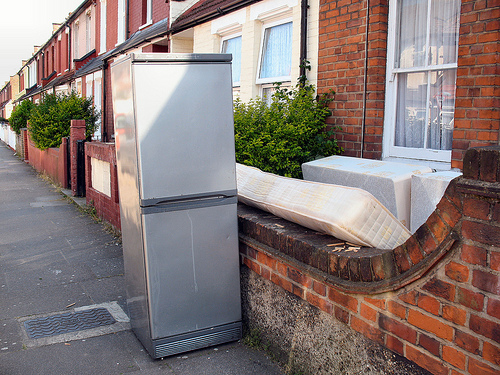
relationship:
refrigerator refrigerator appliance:
[104, 46, 247, 317] [111, 53, 243, 359]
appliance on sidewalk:
[104, 46, 247, 317] [10, 169, 73, 367]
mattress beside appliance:
[235, 158, 410, 259] [101, 50, 248, 357]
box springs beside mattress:
[237, 141, 411, 238] [239, 169, 387, 246]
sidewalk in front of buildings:
[0, 143, 144, 346] [18, 55, 109, 189]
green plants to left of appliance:
[234, 58, 332, 178] [101, 50, 248, 357]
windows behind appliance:
[378, 1, 450, 156] [96, 50, 257, 363]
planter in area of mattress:
[27, 94, 87, 157] [247, 154, 383, 236]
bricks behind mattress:
[462, 71, 493, 103] [254, 163, 396, 253]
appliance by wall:
[111, 53, 243, 359] [76, 141, 479, 365]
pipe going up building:
[357, 1, 371, 157] [174, 5, 484, 247]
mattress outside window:
[235, 158, 410, 259] [383, 2, 462, 165]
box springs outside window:
[237, 141, 411, 238] [383, 2, 462, 165]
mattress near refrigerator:
[235, 158, 410, 259] [106, 50, 241, 360]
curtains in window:
[400, 6, 452, 66] [383, 2, 462, 165]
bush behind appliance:
[6, 98, 35, 127] [111, 53, 243, 359]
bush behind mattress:
[6, 98, 35, 127] [235, 158, 410, 259]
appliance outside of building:
[111, 53, 243, 359] [169, 1, 484, 363]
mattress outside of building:
[235, 158, 410, 259] [169, 1, 484, 363]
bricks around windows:
[462, 71, 493, 103] [378, 1, 450, 156]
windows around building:
[378, 1, 450, 156] [47, 16, 465, 296]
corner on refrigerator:
[124, 52, 191, 109] [73, 38, 254, 358]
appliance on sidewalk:
[111, 53, 243, 359] [35, 255, 108, 335]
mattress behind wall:
[235, 158, 410, 259] [274, 255, 385, 331]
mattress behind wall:
[235, 158, 410, 259] [297, 253, 453, 354]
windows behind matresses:
[378, 1, 450, 156] [226, 156, 409, 241]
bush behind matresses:
[6, 98, 35, 127] [254, 116, 391, 236]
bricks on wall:
[462, 71, 493, 103] [293, 224, 378, 276]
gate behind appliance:
[71, 133, 90, 194] [111, 53, 243, 359]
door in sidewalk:
[132, 59, 243, 192] [13, 206, 83, 351]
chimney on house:
[46, 19, 65, 33] [28, 71, 111, 77]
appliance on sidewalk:
[111, 53, 243, 359] [0, 143, 144, 346]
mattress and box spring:
[235, 158, 410, 259] [313, 145, 438, 235]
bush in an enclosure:
[6, 98, 35, 127] [18, 112, 68, 194]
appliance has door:
[111, 53, 243, 359] [135, 53, 236, 200]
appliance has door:
[111, 53, 243, 359] [138, 200, 241, 341]